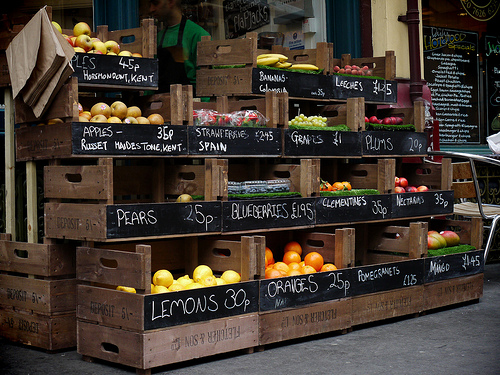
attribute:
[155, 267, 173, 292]
lemon — yellow, round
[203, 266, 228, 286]
lemon — round, yellow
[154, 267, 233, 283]
lemons — bright , yellow 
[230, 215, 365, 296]
fruit — orange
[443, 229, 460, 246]
mango fruit — red, green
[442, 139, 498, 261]
chair — wooden 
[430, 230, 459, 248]
mango fruit — green, red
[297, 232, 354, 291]
fruit — orange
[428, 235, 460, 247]
mango — red, green